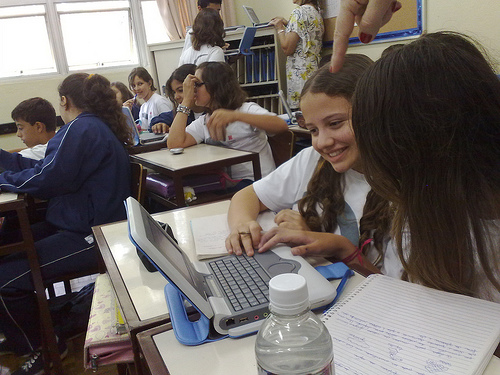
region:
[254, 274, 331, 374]
clear plastic water bottle with white cap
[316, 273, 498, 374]
spiral notebook with blue writing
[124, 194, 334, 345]
white and grey laptop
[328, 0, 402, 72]
hand with red fingernails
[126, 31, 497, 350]
two girls working on a laptop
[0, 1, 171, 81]
three windows on a wall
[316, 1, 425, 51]
cork board on wall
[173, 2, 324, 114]
three standing people working on laptopss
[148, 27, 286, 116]
white book shelf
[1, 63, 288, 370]
several students sitting at desks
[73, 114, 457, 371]
a computer on the table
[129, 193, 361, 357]
a laptop on the table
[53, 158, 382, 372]
a small laptop on the table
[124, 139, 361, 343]
a table with laptop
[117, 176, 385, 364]
a table with computer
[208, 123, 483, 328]
girls on a laptop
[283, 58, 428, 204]
a girl that is smiling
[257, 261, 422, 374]
a bottle on the table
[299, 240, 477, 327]
a notebook on the table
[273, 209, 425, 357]
a notbook onthe desk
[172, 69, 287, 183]
a girl is sitting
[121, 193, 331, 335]
a childrens' laptop computre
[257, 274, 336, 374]
a plastic water bottle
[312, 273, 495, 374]
a notebook that has been written in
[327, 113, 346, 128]
eye of a girl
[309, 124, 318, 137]
eye of a girl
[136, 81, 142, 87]
eye of a girl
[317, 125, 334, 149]
nose of a girl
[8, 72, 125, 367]
a girl is sitting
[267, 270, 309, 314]
lid on a water bottle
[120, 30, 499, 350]
Two girls working on laptop computer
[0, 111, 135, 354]
Dark blue tracksuit worn by girl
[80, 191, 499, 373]
White and brown desks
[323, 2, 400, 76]
Womens hand pointing at girls head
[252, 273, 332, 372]
Clear water bottle with white cap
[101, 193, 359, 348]
White and gray computer in blue case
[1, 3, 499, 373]
Eleven children in a classroom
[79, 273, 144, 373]
White and pink binder sticking out of desk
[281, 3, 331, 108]
White, yellow, and gray dress worn by girl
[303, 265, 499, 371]
Spiral notebook with writing in it